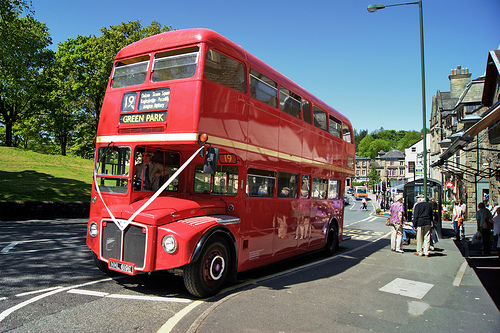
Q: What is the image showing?
A: It is showing a road.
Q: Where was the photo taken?
A: It was taken at the road.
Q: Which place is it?
A: It is a road.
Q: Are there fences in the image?
A: No, there are no fences.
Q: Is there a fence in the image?
A: No, there are no fences.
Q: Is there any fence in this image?
A: No, there are no fences.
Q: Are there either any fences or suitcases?
A: No, there are no fences or suitcases.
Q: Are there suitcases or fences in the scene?
A: No, there are no fences or suitcases.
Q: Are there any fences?
A: No, there are no fences.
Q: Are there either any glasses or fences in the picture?
A: No, there are no fences or glasses.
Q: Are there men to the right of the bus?
A: Yes, there is a man to the right of the bus.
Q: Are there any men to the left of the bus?
A: No, the man is to the right of the bus.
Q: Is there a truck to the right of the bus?
A: No, there is a man to the right of the bus.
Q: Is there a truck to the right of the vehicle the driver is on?
A: No, there is a man to the right of the bus.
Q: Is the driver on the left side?
A: Yes, the driver is on the left of the image.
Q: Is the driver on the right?
A: No, the driver is on the left of the image.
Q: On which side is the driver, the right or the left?
A: The driver is on the left of the image.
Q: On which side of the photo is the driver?
A: The driver is on the left of the image.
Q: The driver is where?
A: The driver is on the bus.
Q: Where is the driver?
A: The driver is on the bus.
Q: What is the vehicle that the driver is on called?
A: The vehicle is a bus.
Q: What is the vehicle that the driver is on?
A: The vehicle is a bus.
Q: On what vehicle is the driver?
A: The driver is on the bus.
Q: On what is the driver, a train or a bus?
A: The driver is on a bus.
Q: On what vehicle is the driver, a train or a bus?
A: The driver is on a bus.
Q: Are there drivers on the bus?
A: Yes, there is a driver on the bus.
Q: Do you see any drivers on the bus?
A: Yes, there is a driver on the bus.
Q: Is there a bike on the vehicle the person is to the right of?
A: No, there is a driver on the bus.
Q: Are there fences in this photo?
A: No, there are no fences.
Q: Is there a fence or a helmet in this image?
A: No, there are no fences or helmets.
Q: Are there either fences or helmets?
A: No, there are no fences or helmets.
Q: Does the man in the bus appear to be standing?
A: Yes, the man is standing.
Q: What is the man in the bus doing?
A: The man is standing.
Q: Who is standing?
A: The man is standing.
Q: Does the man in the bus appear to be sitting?
A: No, the man is standing.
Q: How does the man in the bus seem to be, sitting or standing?
A: The man is standing.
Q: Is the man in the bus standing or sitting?
A: The man is standing.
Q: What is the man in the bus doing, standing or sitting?
A: The man is standing.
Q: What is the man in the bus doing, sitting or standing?
A: The man is standing.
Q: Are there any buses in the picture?
A: Yes, there is a bus.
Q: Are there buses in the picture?
A: Yes, there is a bus.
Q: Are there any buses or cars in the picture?
A: Yes, there is a bus.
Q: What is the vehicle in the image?
A: The vehicle is a bus.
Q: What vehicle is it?
A: The vehicle is a bus.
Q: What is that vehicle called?
A: This is a bus.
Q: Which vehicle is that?
A: This is a bus.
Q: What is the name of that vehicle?
A: This is a bus.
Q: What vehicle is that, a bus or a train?
A: This is a bus.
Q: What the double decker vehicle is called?
A: The vehicle is a bus.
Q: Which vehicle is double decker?
A: The vehicle is a bus.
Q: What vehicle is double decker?
A: The vehicle is a bus.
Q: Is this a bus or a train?
A: This is a bus.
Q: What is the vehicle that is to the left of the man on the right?
A: The vehicle is a bus.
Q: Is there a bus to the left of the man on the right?
A: Yes, there is a bus to the left of the man.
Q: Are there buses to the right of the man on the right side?
A: No, the bus is to the left of the man.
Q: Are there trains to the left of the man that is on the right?
A: No, there is a bus to the left of the man.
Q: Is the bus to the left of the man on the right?
A: Yes, the bus is to the left of the man.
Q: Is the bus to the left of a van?
A: No, the bus is to the left of the man.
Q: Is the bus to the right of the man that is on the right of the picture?
A: No, the bus is to the left of the man.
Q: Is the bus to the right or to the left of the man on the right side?
A: The bus is to the left of the man.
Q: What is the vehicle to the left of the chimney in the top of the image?
A: The vehicle is a bus.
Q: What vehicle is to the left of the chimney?
A: The vehicle is a bus.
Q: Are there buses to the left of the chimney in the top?
A: Yes, there is a bus to the left of the chimney.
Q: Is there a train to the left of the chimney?
A: No, there is a bus to the left of the chimney.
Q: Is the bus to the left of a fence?
A: No, the bus is to the left of a chimney.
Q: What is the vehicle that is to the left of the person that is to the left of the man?
A: The vehicle is a bus.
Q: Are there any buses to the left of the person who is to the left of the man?
A: Yes, there is a bus to the left of the person.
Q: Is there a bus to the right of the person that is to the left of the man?
A: No, the bus is to the left of the person.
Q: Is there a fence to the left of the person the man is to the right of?
A: No, there is a bus to the left of the person.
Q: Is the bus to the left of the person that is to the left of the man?
A: Yes, the bus is to the left of the person.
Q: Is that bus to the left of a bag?
A: No, the bus is to the left of the person.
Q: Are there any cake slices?
A: No, there are no cake slices.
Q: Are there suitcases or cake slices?
A: No, there are no cake slices or suitcases.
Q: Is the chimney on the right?
A: Yes, the chimney is on the right of the image.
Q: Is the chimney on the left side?
A: No, the chimney is on the right of the image.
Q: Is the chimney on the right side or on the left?
A: The chimney is on the right of the image.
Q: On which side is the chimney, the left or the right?
A: The chimney is on the right of the image.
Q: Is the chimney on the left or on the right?
A: The chimney is on the right of the image.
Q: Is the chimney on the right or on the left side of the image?
A: The chimney is on the right of the image.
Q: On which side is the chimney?
A: The chimney is on the right of the image.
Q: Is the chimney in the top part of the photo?
A: Yes, the chimney is in the top of the image.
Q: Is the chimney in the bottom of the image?
A: No, the chimney is in the top of the image.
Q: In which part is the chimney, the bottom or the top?
A: The chimney is in the top of the image.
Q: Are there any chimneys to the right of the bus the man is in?
A: Yes, there is a chimney to the right of the bus.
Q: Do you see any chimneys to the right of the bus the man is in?
A: Yes, there is a chimney to the right of the bus.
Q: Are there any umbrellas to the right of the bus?
A: No, there is a chimney to the right of the bus.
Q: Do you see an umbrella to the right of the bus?
A: No, there is a chimney to the right of the bus.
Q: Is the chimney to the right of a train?
A: No, the chimney is to the right of the bus.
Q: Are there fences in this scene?
A: No, there are no fences.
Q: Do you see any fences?
A: No, there are no fences.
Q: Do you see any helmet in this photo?
A: No, there are no helmets.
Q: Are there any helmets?
A: No, there are no helmets.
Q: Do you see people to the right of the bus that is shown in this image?
A: Yes, there is a person to the right of the bus.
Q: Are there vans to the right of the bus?
A: No, there is a person to the right of the bus.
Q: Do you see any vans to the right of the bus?
A: No, there is a person to the right of the bus.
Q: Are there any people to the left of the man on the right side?
A: Yes, there is a person to the left of the man.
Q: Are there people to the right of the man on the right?
A: No, the person is to the left of the man.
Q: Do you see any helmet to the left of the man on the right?
A: No, there is a person to the left of the man.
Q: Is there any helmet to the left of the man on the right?
A: No, there is a person to the left of the man.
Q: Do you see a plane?
A: No, there are no airplanes.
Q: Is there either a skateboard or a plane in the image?
A: No, there are no airplanes or skateboards.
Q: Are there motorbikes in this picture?
A: No, there are no motorbikes.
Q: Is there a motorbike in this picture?
A: No, there are no motorcycles.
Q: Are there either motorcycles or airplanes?
A: No, there are no motorcycles or airplanes.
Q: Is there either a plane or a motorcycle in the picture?
A: No, there are no motorcycles or airplanes.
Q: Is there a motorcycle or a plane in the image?
A: No, there are no motorcycles or airplanes.